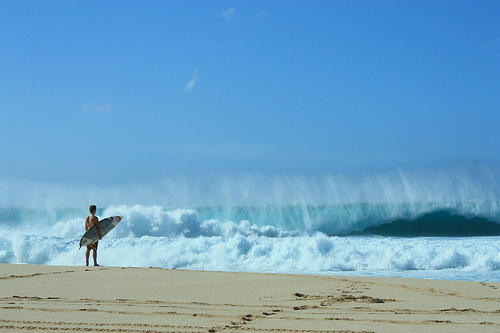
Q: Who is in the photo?
A: Man.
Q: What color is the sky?
A: Blue.